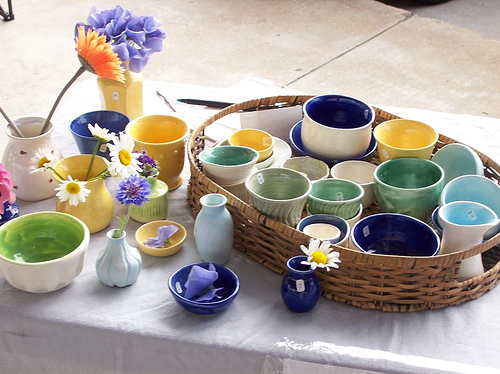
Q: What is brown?
A: A basket.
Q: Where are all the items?
A: On a table.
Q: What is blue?
A: A tiny flower vase.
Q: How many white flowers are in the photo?
A: Five.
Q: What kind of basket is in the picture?
A: Wicker.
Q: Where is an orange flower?
A: In a white vase.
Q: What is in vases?
A: Flowers.